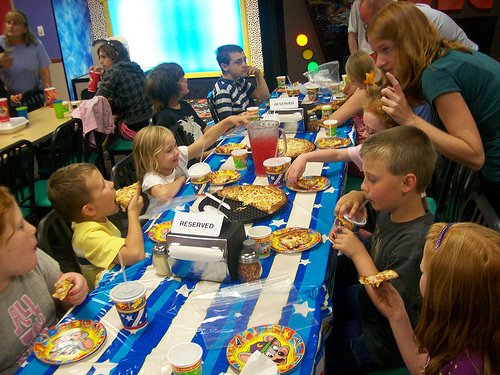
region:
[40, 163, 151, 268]
Child with yellow shirt eating pizza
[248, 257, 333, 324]
Dark blue, aqua and white tablecloth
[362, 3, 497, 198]
Adult talking to child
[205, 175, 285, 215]
Half a pizza on table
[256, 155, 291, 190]
Cup sitting on table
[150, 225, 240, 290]
Napkins in blue and gray napkin holder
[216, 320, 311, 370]
Plate with pizza on it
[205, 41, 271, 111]
Boy with black and white shirt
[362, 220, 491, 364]
Child eating a slice of pizza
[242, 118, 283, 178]
Pitcher of punch drink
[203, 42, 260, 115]
man wearing black and white striped shirt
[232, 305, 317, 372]
a colorful paper plate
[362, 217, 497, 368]
red-haired girl eating pizza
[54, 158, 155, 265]
little boy wearing a yellow shirt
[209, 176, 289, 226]
a half eaten pizza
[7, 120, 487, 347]
kids eating pizza at a long table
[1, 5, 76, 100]
woman wearing a blue T-shirt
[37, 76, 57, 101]
a soft drink with a straw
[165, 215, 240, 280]
a paper napkin dispenser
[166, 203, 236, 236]
a reserved sign on a paper napkin dispenser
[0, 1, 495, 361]
people are sitting around the tables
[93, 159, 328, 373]
the table has white stars on it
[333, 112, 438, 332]
the little boy is drinking from his cup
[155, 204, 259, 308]
a napkin holder is on the table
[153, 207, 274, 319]
the napkin holder says reserved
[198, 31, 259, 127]
the boy's shirt is striped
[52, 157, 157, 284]
the boy is eating a pizza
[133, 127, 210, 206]
the little girl is smiling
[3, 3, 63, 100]
the woman's shirt is blue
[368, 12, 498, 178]
the woman's hair is red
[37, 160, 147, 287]
a child eating pizza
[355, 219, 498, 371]
a child eating pizza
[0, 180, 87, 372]
a child eating pizza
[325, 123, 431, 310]
a child drinking from a cup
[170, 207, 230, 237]
a tented reserved sign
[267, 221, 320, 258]
pizza slice on a paper plate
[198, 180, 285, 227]
half of a pizza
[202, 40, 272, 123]
a boy wearing a blue and white striped shirt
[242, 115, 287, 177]
a pitcher of red soda